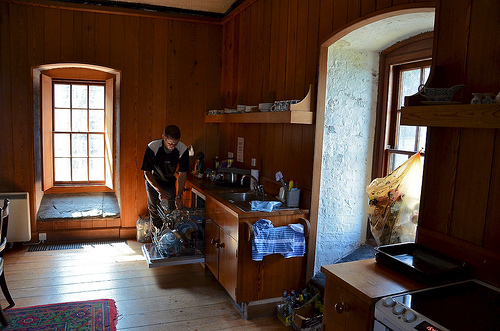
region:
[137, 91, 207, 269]
Man placing dishes in dishwasher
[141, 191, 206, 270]
Dishwasher filled with dirty dishes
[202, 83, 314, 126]
Cups on wall cupboard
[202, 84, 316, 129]
Wooden shelf on the wall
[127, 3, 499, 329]
Man in the kitchen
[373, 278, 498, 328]
White electric range against the wall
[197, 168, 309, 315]
Kitchen sink in wood counter top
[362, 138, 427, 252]
Bag of trash hanging on a nail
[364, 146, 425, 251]
Plastic bag hanging on the wall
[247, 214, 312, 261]
Blue and white towel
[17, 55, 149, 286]
arched window with no shades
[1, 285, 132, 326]
area rug on wooden floor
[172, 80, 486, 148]
two shelves in photograph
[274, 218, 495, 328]
oven range in photograph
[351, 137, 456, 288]
bag hanging on wall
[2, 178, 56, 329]
back of chair visible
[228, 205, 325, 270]
blue towel on towel rack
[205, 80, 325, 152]
dishes on shelf above sink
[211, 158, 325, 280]
kitchen sink visible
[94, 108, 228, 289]
man doing something in kitchen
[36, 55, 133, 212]
the window behind the man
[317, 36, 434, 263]
The window to the right of the man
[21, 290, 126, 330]
a multi colored carpet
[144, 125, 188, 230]
a man putting dishes in a dishwasher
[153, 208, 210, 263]
a dishwasher full of dishes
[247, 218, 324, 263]
a blue kitchen towel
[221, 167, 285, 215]
a kitchen sink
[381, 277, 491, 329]
a modern looking stove top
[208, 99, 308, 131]
group of dishes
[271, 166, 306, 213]
a container for holding utensils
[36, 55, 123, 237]
the window has wooden shutters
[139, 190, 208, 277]
a dishwasher is in the kitchen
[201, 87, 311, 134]
a wooden shelf has bowls and cups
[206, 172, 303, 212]
a kitchen sink has a silver faucet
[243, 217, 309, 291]
a blue and white towel hangs on a rack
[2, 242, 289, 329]
the floors are wooden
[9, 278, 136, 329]
a fringed rug is on the floor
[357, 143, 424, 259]
a plastic bag is hanging in the window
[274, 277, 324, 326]
boxes of items are on the floor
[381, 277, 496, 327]
a smooth top stove is in the kitchen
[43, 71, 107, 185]
a window with light coming in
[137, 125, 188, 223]
a man standing by the dishwasher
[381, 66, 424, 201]
another window with light coming in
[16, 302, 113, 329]
a little rug on the ground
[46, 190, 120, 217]
a spot to sit at by the window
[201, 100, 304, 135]
a shelf with a bunch of cups and plates on it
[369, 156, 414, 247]
a bag filled with trash on the wall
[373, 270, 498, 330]
a stove and oven by the wall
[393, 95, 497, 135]
another shelf by the wall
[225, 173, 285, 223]
a sink in the kitchen